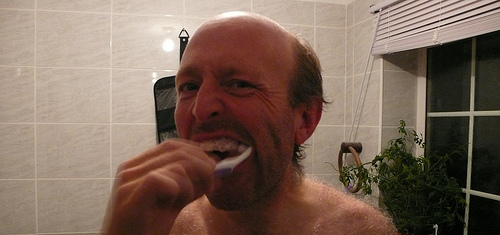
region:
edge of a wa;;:
[376, 98, 396, 123]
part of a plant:
[396, 174, 423, 211]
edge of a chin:
[221, 192, 247, 224]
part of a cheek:
[270, 134, 287, 156]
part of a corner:
[341, 94, 358, 127]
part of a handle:
[353, 127, 365, 162]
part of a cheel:
[247, 122, 290, 175]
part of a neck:
[281, 178, 306, 208]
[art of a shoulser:
[367, 199, 374, 230]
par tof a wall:
[96, 52, 166, 136]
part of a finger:
[191, 157, 207, 192]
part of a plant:
[397, 148, 421, 201]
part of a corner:
[341, 68, 354, 98]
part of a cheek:
[246, 85, 295, 169]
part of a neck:
[278, 186, 302, 223]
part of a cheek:
[253, 108, 268, 131]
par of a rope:
[345, 67, 380, 154]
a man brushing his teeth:
[153, 14, 334, 213]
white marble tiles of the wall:
[11, 45, 116, 169]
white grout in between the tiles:
[23, 48, 49, 137]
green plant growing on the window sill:
[367, 142, 458, 224]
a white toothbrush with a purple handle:
[207, 139, 254, 186]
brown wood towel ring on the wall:
[333, 137, 364, 190]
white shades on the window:
[352, 5, 498, 47]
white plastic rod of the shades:
[343, 13, 382, 137]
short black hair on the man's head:
[288, 40, 328, 113]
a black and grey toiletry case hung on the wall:
[148, 31, 199, 146]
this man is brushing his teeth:
[90, 9, 420, 234]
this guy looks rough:
[55, 5, 419, 233]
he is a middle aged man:
[112, 4, 349, 215]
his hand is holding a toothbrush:
[91, 144, 281, 214]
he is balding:
[214, 4, 346, 109]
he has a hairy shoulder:
[312, 179, 393, 233]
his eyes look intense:
[168, 67, 265, 101]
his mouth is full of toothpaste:
[181, 126, 275, 171]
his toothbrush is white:
[202, 149, 276, 195]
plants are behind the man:
[366, 138, 473, 228]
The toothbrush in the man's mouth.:
[202, 145, 256, 171]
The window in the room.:
[410, 43, 498, 234]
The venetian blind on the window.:
[375, 0, 498, 52]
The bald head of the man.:
[182, 13, 292, 69]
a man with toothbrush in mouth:
[110, 12, 396, 232]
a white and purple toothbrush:
[210, 145, 250, 170]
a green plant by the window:
[335, 122, 465, 232]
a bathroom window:
[425, 27, 496, 232]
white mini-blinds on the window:
[370, 0, 496, 52]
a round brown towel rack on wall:
[335, 138, 363, 189]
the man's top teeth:
[191, 137, 246, 153]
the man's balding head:
[175, 10, 325, 210]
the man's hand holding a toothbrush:
[101, 140, 217, 230]